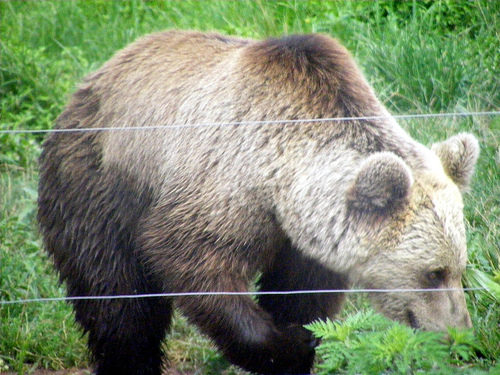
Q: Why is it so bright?
A: Sunny.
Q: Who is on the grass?
A: The bear.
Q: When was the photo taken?
A: Day time.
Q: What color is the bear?
A: Brown.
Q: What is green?
A: The grass.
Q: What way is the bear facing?
A: Right.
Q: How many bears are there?
A: One.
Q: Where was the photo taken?
A: In a zoo.